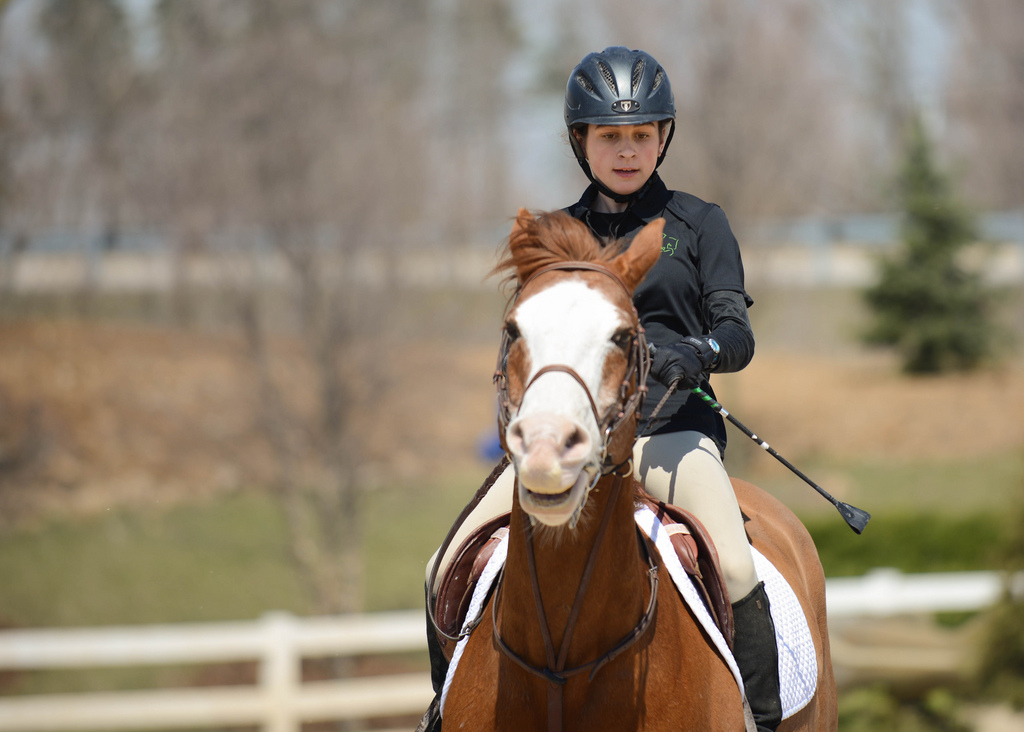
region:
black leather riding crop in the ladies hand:
[646, 353, 885, 538]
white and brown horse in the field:
[418, 211, 834, 727]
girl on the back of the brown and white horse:
[418, 42, 881, 697]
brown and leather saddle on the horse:
[419, 486, 739, 671]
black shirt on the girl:
[500, 177, 760, 438]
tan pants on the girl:
[425, 429, 773, 616]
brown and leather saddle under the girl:
[435, 503, 733, 665]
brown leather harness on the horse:
[478, 265, 660, 725]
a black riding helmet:
[561, 42, 686, 207]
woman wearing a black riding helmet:
[419, 31, 865, 730]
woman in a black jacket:
[520, 44, 786, 730]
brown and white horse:
[427, 205, 842, 728]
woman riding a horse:
[425, 42, 859, 729]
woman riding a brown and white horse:
[415, 37, 845, 721]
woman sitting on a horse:
[424, 37, 849, 730]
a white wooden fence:
[5, 563, 1021, 729]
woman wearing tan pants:
[416, 47, 775, 592]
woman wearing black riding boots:
[416, 45, 793, 729]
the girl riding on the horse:
[421, 48, 836, 729]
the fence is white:
[1, 568, 1017, 728]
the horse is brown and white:
[431, 202, 836, 728]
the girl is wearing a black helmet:
[419, 48, 783, 729]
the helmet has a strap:
[560, 45, 677, 202]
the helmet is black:
[566, 44, 678, 204]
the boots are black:
[418, 575, 782, 730]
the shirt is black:
[539, 171, 752, 457]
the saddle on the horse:
[433, 205, 836, 730]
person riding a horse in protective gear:
[419, 44, 790, 730]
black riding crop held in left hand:
[629, 331, 880, 531]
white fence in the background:
[7, 569, 1014, 729]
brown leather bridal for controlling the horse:
[491, 250, 679, 539]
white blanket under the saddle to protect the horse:
[437, 500, 839, 713]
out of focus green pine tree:
[855, 104, 1015, 395]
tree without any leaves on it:
[122, 7, 424, 726]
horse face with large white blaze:
[492, 199, 666, 533]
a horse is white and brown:
[388, 201, 866, 729]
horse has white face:
[451, 197, 682, 545]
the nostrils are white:
[490, 394, 602, 475]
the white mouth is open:
[495, 457, 598, 541]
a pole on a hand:
[637, 340, 904, 559]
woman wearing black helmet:
[464, 15, 768, 330]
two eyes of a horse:
[480, 305, 640, 366]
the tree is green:
[830, 91, 1023, 411]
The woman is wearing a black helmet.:
[541, 51, 690, 141]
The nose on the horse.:
[514, 417, 597, 478]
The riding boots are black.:
[730, 584, 785, 717]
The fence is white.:
[29, 607, 403, 705]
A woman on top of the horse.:
[547, 48, 776, 558]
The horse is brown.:
[397, 407, 692, 728]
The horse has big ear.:
[597, 214, 705, 287]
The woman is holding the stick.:
[663, 367, 898, 529]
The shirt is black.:
[571, 190, 737, 315]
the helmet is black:
[569, 46, 678, 122]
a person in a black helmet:
[565, 64, 714, 331]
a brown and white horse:
[411, 244, 826, 713]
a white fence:
[22, 584, 1012, 718]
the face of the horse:
[489, 233, 642, 529]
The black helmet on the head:
[558, 42, 677, 125]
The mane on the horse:
[477, 206, 632, 296]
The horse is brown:
[423, 199, 834, 727]